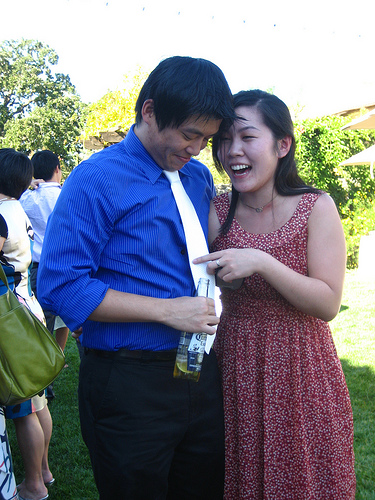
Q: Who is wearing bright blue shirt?
A: Man with white tie.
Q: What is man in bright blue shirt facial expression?
A: Smiling.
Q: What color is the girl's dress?
A: Red.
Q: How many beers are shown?
A: 1.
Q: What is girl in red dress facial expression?
A: Laughing.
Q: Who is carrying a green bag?
A: Person off to side.